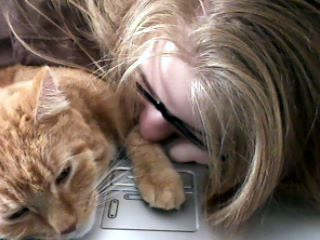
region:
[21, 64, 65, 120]
Ear of an orange cat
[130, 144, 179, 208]
Paw of a cat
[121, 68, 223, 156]
Pair of black eyeglasses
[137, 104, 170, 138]
Young girl's nose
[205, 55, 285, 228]
Lock of long blonde hair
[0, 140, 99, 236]
Orange kitty's face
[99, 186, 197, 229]
Computer track pad with paw on it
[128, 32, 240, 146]
Face of young girl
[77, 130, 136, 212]
Cat's whiskers in front of computer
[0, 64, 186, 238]
Cuddly orange cat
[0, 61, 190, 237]
cat laying on keyboard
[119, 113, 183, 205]
cats paw is on the mousepad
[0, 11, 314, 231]
woman laying down next to cat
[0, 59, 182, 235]
orange cat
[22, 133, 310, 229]
silver laptop keyboard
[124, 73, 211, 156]
woman is wearing black glasses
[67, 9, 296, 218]
woman has blonde hair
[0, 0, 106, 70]
woman is wearing brown jacket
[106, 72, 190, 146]
woman has nose against cat's leg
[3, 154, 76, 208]
cat is looking forward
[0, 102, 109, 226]
cat laying with owner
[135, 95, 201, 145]
glasses on the woman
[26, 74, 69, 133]
ear of the cat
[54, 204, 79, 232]
nose of the cat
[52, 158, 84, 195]
eye of the cat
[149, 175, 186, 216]
paw of the cat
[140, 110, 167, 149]
nose of the woman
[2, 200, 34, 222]
eye of the cat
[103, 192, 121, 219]
button on the laptop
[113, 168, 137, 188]
button on the mousepad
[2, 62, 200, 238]
adult orange cat with short hair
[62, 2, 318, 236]
woman with blonde hair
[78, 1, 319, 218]
woman wearing black glasses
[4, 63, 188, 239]
cat laying on a computer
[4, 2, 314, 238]
woman and a cat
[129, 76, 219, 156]
glasses with black frames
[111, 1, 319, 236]
woman laying on a computer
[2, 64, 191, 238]
large orange cat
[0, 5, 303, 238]
woman and cat on a computer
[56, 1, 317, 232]
woman with long blonde hair